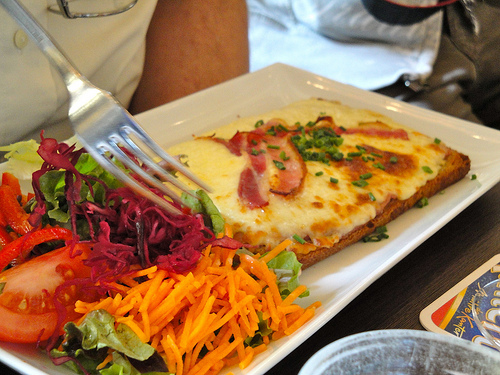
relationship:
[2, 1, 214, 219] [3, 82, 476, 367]
fork digging into a lunch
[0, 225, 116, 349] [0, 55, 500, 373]
tomato on plate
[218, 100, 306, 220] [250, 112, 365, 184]
bacon has chives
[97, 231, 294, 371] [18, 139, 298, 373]
carrots on lettuce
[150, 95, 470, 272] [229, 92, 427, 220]
bread has chives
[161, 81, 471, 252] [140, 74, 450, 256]
bread topped with cheese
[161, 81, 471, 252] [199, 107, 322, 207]
bread topped with bacon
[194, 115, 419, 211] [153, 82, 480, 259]
bacon on pizza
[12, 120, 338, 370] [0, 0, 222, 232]
cabbage under fork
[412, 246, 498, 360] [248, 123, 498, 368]
coaster on table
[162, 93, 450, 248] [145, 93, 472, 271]
cheese on pizza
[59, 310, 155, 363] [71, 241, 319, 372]
lettuce leaf by carrots